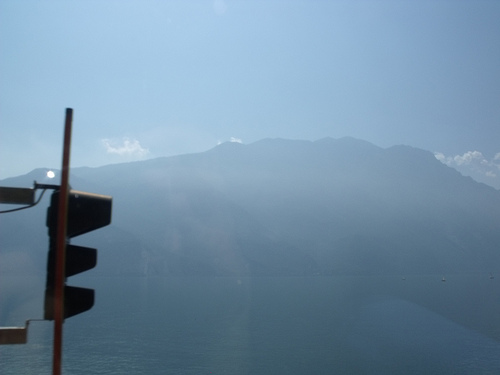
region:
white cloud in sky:
[101, 129, 154, 157]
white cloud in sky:
[446, 147, 495, 177]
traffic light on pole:
[48, 107, 103, 327]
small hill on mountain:
[211, 132, 248, 155]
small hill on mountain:
[251, 127, 296, 145]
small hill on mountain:
[318, 134, 338, 149]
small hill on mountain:
[336, 127, 358, 148]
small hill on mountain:
[349, 135, 379, 155]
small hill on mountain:
[393, 141, 410, 158]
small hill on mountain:
[409, 143, 434, 166]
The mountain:
[216, 153, 454, 270]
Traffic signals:
[57, 173, 121, 329]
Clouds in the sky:
[443, 147, 498, 178]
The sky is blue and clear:
[180, 13, 338, 88]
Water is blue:
[156, 287, 301, 348]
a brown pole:
[52, 112, 90, 170]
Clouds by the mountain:
[207, 130, 242, 145]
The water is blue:
[212, 280, 374, 357]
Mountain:
[241, 136, 433, 251]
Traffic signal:
[46, 175, 106, 328]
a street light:
[0, 149, 173, 342]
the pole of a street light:
[19, 107, 101, 373]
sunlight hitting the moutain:
[79, 60, 307, 319]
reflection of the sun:
[30, 160, 65, 192]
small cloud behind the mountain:
[92, 121, 168, 186]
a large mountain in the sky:
[88, 79, 461, 323]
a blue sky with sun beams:
[165, 23, 412, 123]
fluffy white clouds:
[409, 127, 496, 197]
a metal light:
[0, 165, 137, 357]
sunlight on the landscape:
[7, 25, 467, 370]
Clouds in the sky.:
[94, 113, 191, 189]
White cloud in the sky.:
[121, 92, 269, 173]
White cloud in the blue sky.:
[105, 120, 173, 192]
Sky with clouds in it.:
[156, 72, 421, 287]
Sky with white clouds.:
[159, 76, 425, 242]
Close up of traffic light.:
[27, 135, 157, 367]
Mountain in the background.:
[218, 99, 469, 318]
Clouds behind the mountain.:
[398, 112, 498, 219]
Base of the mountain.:
[147, 296, 307, 366]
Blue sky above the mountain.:
[116, 115, 446, 192]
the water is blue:
[156, 348, 173, 368]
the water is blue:
[179, 342, 199, 369]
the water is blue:
[175, 342, 187, 372]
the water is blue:
[169, 361, 189, 373]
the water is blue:
[182, 339, 210, 368]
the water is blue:
[169, 348, 176, 360]